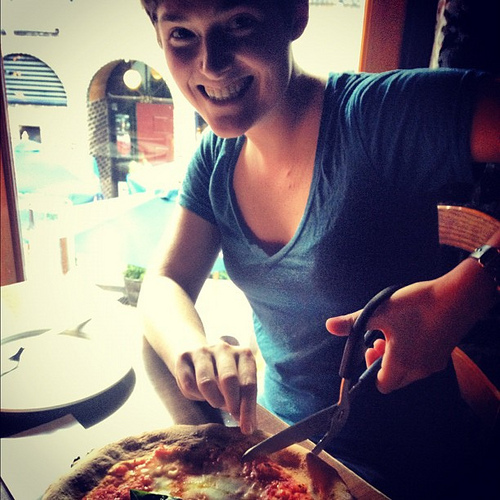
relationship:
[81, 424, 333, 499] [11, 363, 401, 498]
pizza on counter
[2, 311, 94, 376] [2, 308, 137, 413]
fork in plate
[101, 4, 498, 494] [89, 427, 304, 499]
woman cutting pizza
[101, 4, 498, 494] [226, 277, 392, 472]
woman cutting with shears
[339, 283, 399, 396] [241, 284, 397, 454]
handles on shears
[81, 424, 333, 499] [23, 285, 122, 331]
pizza on table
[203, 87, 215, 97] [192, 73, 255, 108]
white tooth in mouth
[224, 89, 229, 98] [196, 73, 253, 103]
tooth in mouth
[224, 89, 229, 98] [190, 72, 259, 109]
tooth in mouth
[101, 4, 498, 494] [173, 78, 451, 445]
woman wearing shirt